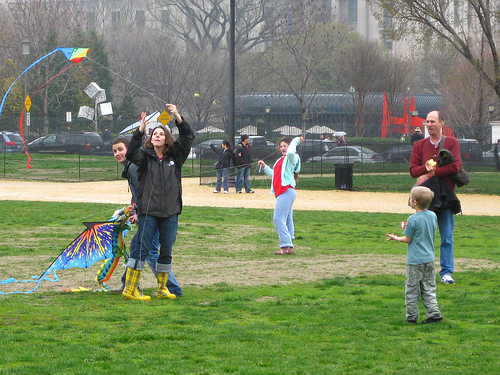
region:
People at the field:
[70, 90, 475, 319]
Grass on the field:
[252, 279, 391, 363]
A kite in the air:
[6, 24, 182, 140]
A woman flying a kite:
[2, 30, 211, 293]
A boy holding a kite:
[355, 183, 441, 325]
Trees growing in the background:
[168, 16, 353, 109]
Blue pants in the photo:
[273, 189, 296, 245]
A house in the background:
[259, 91, 386, 132]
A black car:
[33, 125, 110, 162]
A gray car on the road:
[316, 138, 384, 170]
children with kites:
[50, 83, 238, 317]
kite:
[30, 21, 95, 72]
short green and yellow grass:
[231, 305, 249, 320]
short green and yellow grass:
[267, 275, 321, 330]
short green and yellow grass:
[325, 311, 370, 373]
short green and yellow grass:
[235, 336, 299, 373]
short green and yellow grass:
[167, 341, 224, 372]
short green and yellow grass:
[107, 331, 179, 373]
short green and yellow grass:
[71, 321, 153, 371]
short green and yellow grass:
[360, 318, 421, 338]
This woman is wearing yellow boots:
[125, 275, 164, 327]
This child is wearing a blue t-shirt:
[417, 213, 428, 248]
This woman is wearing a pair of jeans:
[163, 250, 175, 285]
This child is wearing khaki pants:
[400, 308, 425, 366]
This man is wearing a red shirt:
[423, 140, 430, 160]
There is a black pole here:
[228, 80, 239, 110]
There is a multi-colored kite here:
[66, 225, 83, 300]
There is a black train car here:
[348, 84, 362, 139]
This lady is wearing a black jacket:
[163, 190, 175, 230]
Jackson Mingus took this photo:
[106, 94, 266, 364]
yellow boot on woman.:
[127, 272, 136, 289]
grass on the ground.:
[345, 318, 369, 343]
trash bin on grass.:
[337, 164, 352, 184]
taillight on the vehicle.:
[85, 141, 91, 150]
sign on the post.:
[158, 110, 169, 123]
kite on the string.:
[52, 45, 89, 70]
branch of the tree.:
[456, 35, 472, 62]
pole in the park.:
[227, 46, 237, 76]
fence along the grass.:
[365, 148, 383, 166]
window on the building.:
[344, 3, 355, 23]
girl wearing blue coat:
[254, 125, 308, 258]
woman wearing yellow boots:
[127, 96, 187, 303]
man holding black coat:
[415, 109, 463, 284]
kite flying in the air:
[6, 40, 93, 96]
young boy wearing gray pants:
[380, 184, 446, 318]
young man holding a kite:
[105, 137, 182, 308]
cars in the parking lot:
[2, 112, 499, 164]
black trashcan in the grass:
[327, 156, 354, 188]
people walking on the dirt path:
[208, 131, 255, 189]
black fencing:
[8, 133, 490, 177]